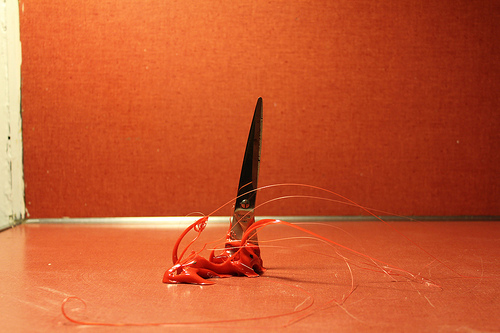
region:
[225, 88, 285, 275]
scissors are made of metal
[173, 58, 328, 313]
scissors are made of metal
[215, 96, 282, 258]
the scissors are silver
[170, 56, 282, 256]
the scissors are silver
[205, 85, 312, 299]
the scissors are silver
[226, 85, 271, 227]
silver blades of a pair of scissors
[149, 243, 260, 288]
melted handle of a pair of scissors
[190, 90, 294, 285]
scissors with a melted handle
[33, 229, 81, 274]
orange floor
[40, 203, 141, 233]
light coming under the door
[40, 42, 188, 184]
wooden door behind the scissors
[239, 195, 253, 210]
rivet on the scissor blades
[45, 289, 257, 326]
melted plastic string from the handle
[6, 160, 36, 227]
wooden door frame with paint peeling at the bottom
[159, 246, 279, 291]
melted plastic scissor handles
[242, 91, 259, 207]
The blades of the scissors.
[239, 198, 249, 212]
The screw of the scissors.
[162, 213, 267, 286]
The melted handles of the scissors.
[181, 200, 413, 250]
The melted plastic shaped into curved lines.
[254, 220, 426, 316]
The melted plastic shaped into string like lines.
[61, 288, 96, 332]
The melted plastic shaped into a curl.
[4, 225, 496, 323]
The red floor the scissors are melted on.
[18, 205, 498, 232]
The gray border of the red wall.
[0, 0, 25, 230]
The white wall on the left.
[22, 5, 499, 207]
The red wall in the room.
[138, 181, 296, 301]
an orange melted platic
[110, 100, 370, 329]
an orange melted platic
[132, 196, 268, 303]
the plastic is melted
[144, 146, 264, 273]
the plastic is melted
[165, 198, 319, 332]
the plastic is melted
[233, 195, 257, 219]
the screw is silver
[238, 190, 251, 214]
the screw is silver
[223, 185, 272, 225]
the screw is silver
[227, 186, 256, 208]
the screw is silver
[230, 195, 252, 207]
the screw is silver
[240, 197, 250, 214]
the screw is metal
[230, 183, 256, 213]
the screw is metal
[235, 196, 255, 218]
the screw is metal